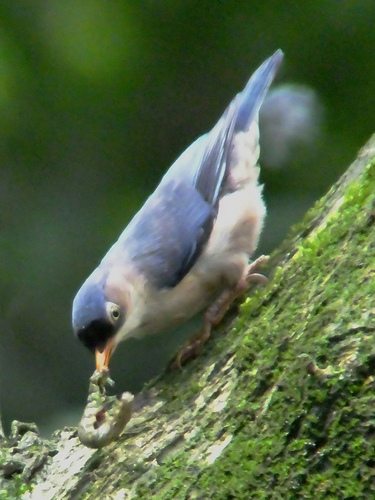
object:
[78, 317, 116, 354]
spot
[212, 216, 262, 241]
wheel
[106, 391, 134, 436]
tail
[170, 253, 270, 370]
foot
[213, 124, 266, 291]
white underside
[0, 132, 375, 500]
surface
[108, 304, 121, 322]
eye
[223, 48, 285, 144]
tail feathers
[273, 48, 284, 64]
edge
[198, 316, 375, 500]
grass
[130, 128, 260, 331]
feathers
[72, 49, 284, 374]
bird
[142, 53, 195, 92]
wall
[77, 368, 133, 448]
caterpillar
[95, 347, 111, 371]
beak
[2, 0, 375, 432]
green background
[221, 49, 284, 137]
tail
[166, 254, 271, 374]
branch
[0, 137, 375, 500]
trunk